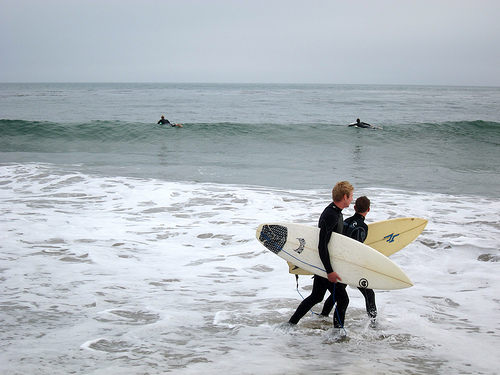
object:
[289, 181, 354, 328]
man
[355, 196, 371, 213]
hair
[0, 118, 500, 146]
wave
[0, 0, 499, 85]
sky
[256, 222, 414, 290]
surfboard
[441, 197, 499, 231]
ground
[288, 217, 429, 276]
board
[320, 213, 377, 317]
wet suit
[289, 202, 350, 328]
wet suit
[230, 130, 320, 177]
water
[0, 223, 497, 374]
beach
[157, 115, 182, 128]
people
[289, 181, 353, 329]
surfer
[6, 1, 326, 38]
cloudy sky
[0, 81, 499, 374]
ocean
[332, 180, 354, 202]
hair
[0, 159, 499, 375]
foam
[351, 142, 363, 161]
reflection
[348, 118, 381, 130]
people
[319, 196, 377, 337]
man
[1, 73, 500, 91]
horizon